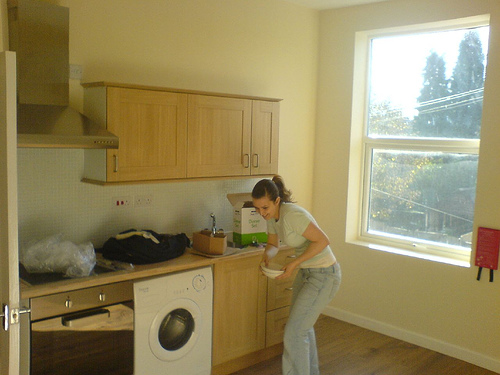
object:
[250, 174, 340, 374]
woman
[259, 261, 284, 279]
bowl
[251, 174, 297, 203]
hair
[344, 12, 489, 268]
window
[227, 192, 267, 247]
box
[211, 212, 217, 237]
faucet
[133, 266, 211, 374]
washer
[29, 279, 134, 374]
dishwasher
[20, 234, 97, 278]
bag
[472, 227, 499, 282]
sign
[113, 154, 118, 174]
handle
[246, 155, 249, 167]
handle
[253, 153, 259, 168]
handle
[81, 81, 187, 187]
cabinet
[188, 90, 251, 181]
cabinet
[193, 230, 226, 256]
cardboard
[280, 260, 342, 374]
jeans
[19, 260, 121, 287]
stove top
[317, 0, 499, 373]
wall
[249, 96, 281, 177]
cabinet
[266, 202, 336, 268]
shirt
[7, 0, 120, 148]
vent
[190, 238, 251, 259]
sink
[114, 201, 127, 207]
switch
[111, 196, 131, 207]
plate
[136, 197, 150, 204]
outlet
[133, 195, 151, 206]
plate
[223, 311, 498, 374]
flooring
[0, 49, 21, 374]
door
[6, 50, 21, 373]
edge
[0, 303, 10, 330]
handle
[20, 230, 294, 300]
counter top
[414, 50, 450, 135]
tree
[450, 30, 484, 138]
tree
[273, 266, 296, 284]
hand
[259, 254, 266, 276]
hand